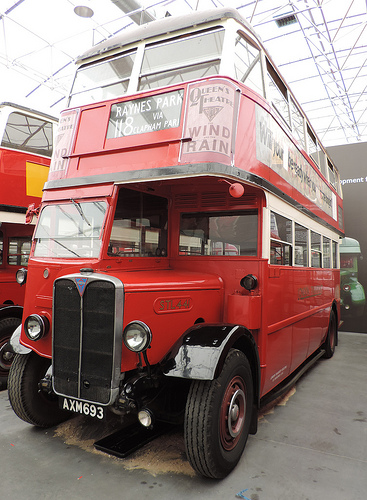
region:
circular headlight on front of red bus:
[119, 317, 153, 351]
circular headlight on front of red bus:
[23, 310, 47, 343]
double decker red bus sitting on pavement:
[7, 8, 345, 479]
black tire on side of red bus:
[181, 343, 253, 477]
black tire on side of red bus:
[4, 346, 69, 428]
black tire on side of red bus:
[324, 305, 336, 361]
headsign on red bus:
[101, 89, 184, 137]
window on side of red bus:
[265, 207, 296, 274]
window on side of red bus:
[293, 217, 310, 270]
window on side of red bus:
[321, 231, 334, 272]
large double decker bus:
[9, 35, 351, 482]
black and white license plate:
[60, 395, 111, 420]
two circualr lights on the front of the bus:
[14, 310, 152, 363]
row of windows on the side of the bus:
[260, 207, 357, 269]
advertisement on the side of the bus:
[252, 113, 349, 218]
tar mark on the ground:
[332, 423, 341, 438]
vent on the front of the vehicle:
[47, 279, 129, 415]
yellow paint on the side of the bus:
[26, 162, 55, 199]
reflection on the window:
[32, 204, 106, 267]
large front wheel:
[176, 347, 265, 485]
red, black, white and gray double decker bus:
[8, 7, 342, 483]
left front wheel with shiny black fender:
[156, 322, 255, 488]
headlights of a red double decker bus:
[22, 311, 150, 359]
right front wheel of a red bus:
[9, 350, 68, 431]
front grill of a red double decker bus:
[51, 271, 121, 408]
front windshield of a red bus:
[180, 209, 260, 267]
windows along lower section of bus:
[265, 214, 341, 272]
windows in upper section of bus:
[231, 29, 339, 199]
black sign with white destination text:
[105, 89, 187, 142]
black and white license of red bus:
[57, 393, 109, 427]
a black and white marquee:
[105, 101, 184, 146]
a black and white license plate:
[56, 393, 110, 420]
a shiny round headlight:
[139, 405, 151, 425]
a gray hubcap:
[225, 391, 248, 438]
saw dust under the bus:
[144, 442, 172, 472]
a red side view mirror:
[219, 175, 251, 207]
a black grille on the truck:
[46, 273, 108, 402]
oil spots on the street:
[137, 477, 161, 492]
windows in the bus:
[268, 202, 342, 272]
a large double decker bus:
[8, 14, 354, 468]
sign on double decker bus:
[179, 75, 251, 168]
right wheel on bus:
[164, 344, 275, 483]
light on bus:
[132, 404, 157, 430]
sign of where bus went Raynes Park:
[90, 81, 186, 158]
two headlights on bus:
[0, 308, 160, 356]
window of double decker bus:
[30, 195, 118, 268]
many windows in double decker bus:
[258, 208, 341, 274]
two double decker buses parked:
[2, 6, 349, 487]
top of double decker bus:
[3, 0, 356, 180]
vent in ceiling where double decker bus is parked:
[265, 9, 313, 29]